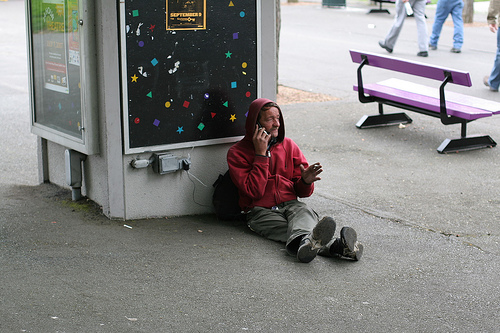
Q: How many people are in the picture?
A: One.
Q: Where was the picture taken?
A: On the sidewalk.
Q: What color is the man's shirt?
A: Red.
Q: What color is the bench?
A: Purple.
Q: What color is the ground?
A: Gray.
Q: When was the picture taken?
A: In the daytime.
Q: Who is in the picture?
A: A man.